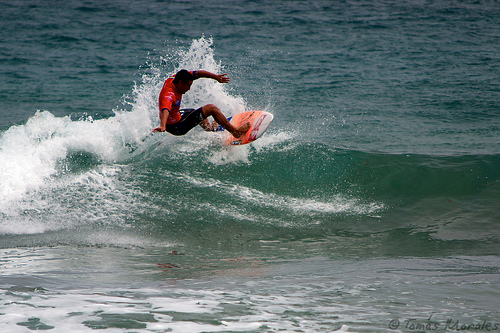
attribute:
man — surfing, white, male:
[151, 66, 254, 137]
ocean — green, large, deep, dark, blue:
[1, 1, 496, 331]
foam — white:
[2, 37, 299, 221]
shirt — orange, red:
[156, 67, 198, 125]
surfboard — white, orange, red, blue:
[192, 111, 276, 147]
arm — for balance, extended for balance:
[188, 68, 229, 85]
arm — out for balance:
[155, 85, 179, 133]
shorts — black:
[167, 105, 208, 136]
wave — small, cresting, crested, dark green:
[2, 124, 499, 230]